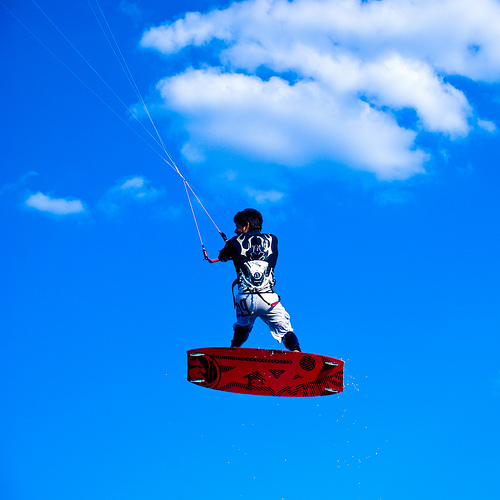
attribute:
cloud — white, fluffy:
[19, 188, 87, 222]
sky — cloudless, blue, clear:
[1, 0, 498, 498]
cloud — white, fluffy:
[151, 66, 433, 186]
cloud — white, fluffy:
[134, 2, 499, 144]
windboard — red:
[186, 345, 345, 401]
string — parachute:
[23, 2, 229, 252]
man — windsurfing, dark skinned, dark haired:
[218, 208, 303, 356]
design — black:
[196, 353, 219, 392]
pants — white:
[233, 289, 299, 346]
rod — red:
[198, 232, 231, 266]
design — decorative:
[235, 234, 274, 283]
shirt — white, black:
[214, 233, 280, 290]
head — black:
[231, 208, 266, 237]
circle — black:
[297, 353, 318, 374]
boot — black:
[281, 331, 304, 353]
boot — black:
[229, 328, 253, 348]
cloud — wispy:
[101, 174, 163, 217]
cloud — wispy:
[220, 162, 289, 209]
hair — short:
[233, 209, 265, 235]